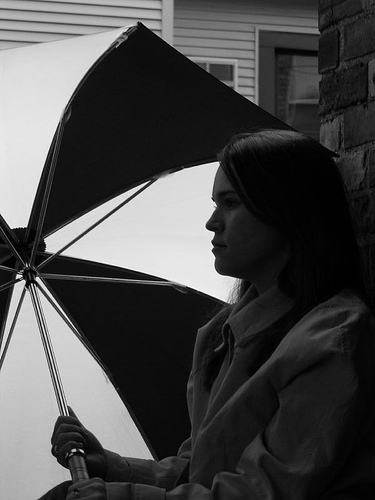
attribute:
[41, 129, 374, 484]
woman — seated, protecting, sitting, staring, to the left, siting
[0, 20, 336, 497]
umbrella — large, for two people, black, white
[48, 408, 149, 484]
hand — wrapped, curled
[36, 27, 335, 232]
umbrella panels — dark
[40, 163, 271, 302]
umbrella panels — light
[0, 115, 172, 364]
rods — metal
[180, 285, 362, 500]
raincoat — long, gray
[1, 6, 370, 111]
house — clapboard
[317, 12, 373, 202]
bricks — gray, white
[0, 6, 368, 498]
photo — black, white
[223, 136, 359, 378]
hair — long, dark, black, beautiful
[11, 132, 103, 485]
spoke — silver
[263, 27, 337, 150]
glass door — black, white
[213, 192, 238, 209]
eye — black, white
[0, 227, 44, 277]
piece — plastic, small, black